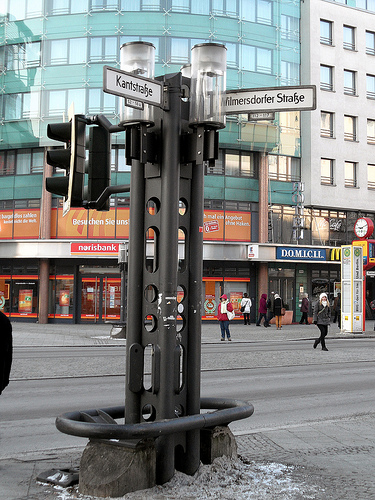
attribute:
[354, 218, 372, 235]
red clock — tall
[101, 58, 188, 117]
sign — street sign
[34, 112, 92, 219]
traffic light — black 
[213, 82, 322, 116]
sign — blue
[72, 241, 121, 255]
sign — red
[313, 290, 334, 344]
woman — walking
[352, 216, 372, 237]
clock — white, red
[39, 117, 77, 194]
light — traffic light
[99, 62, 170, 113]
sign — direction sign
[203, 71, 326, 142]
sign — white, gray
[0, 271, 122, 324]
windows — red, bordered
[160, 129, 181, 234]
post — metal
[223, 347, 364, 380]
road — gray, tarmac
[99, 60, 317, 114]
signs — street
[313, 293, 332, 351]
woman — walking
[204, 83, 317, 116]
sign post — direction sign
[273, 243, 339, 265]
sign — blue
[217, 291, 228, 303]
hat — red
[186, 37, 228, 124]
light — cylindrical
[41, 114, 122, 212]
signal — traffic light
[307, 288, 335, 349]
someone — walking